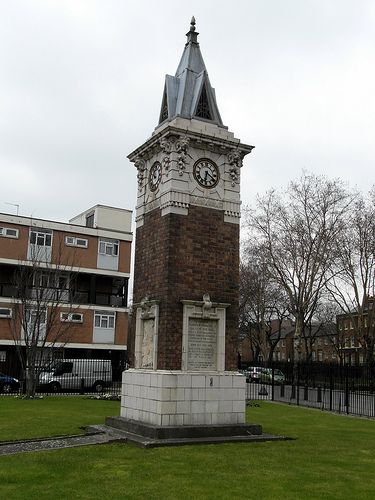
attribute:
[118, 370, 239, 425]
base — white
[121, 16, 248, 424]
tower — small, brown, brick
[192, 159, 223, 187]
clock — black, white, brown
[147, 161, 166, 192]
clock — black, white, brown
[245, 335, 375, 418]
fence — black, wrought iron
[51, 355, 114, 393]
van — white, parked, black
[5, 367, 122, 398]
street — gray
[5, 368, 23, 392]
car — blue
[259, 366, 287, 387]
car — green, light green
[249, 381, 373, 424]
street — gray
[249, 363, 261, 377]
suv — silver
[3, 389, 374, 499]
grass — green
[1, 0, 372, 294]
sky — white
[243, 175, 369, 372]
trees — bare